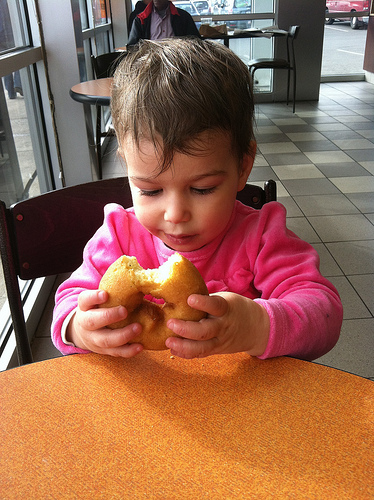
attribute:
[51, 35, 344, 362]
girl — pink, little, young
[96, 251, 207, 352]
donut — light brown, large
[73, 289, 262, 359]
hands — little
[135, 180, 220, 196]
eyes — open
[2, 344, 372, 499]
table — orange, golden brown, speckled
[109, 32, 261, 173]
hair — brown, dark brown, short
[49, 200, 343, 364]
shirt — pink, long sleeve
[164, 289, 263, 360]
hand — chubby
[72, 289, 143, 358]
hand — chubby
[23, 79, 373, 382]
tile floor — white, grey, checkered, multicolored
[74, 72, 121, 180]
table — orange, golden brown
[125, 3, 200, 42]
jacket — red, black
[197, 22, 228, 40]
paper bag — brown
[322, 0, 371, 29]
truck — red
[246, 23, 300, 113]
chair — tall, black, metal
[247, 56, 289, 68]
cushion — black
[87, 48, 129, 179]
chair — tall, black